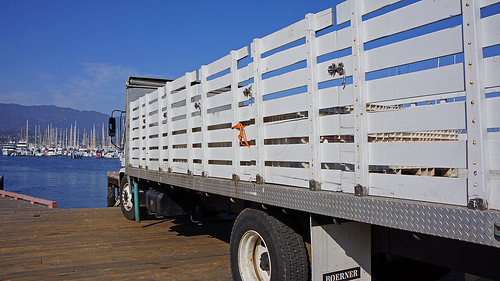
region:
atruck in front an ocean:
[91, 2, 498, 278]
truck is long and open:
[97, 2, 498, 278]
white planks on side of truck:
[126, 3, 498, 203]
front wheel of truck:
[110, 169, 151, 223]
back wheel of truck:
[221, 201, 313, 278]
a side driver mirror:
[105, 102, 130, 155]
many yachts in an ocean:
[0, 114, 121, 166]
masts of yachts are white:
[6, 110, 124, 161]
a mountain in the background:
[1, 97, 116, 131]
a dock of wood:
[1, 181, 298, 278]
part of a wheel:
[261, 217, 309, 257]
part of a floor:
[126, 217, 168, 255]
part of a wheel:
[221, 209, 289, 276]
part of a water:
[57, 156, 94, 184]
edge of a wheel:
[247, 210, 277, 245]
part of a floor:
[83, 187, 133, 241]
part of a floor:
[115, 222, 151, 254]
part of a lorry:
[292, 51, 347, 126]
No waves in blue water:
[9, 161, 107, 203]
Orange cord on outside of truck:
[229, 121, 254, 148]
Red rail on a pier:
[2, 187, 59, 215]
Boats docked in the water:
[14, 122, 114, 159]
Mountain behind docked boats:
[0, 100, 120, 143]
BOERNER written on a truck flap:
[323, 266, 368, 278]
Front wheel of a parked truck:
[116, 175, 138, 218]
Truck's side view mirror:
[108, 115, 119, 135]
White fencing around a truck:
[130, 61, 488, 202]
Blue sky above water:
[20, 6, 221, 51]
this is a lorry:
[197, 83, 469, 187]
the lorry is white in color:
[216, 80, 386, 108]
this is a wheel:
[224, 217, 296, 264]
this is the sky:
[27, 9, 184, 56]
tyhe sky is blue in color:
[50, 12, 117, 34]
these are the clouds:
[73, 66, 107, 93]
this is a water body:
[36, 158, 86, 177]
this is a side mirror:
[108, 113, 116, 132]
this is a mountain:
[16, 104, 78, 120]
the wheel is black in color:
[268, 214, 289, 256]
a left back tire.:
[205, 192, 308, 278]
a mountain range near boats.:
[0, 96, 130, 154]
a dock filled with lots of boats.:
[0, 119, 125, 163]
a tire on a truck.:
[103, 181, 154, 223]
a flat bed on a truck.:
[128, 0, 498, 215]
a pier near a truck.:
[0, 178, 61, 210]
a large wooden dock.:
[2, 201, 235, 277]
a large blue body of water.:
[0, 157, 124, 206]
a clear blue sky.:
[4, 0, 498, 120]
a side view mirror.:
[86, 97, 127, 154]